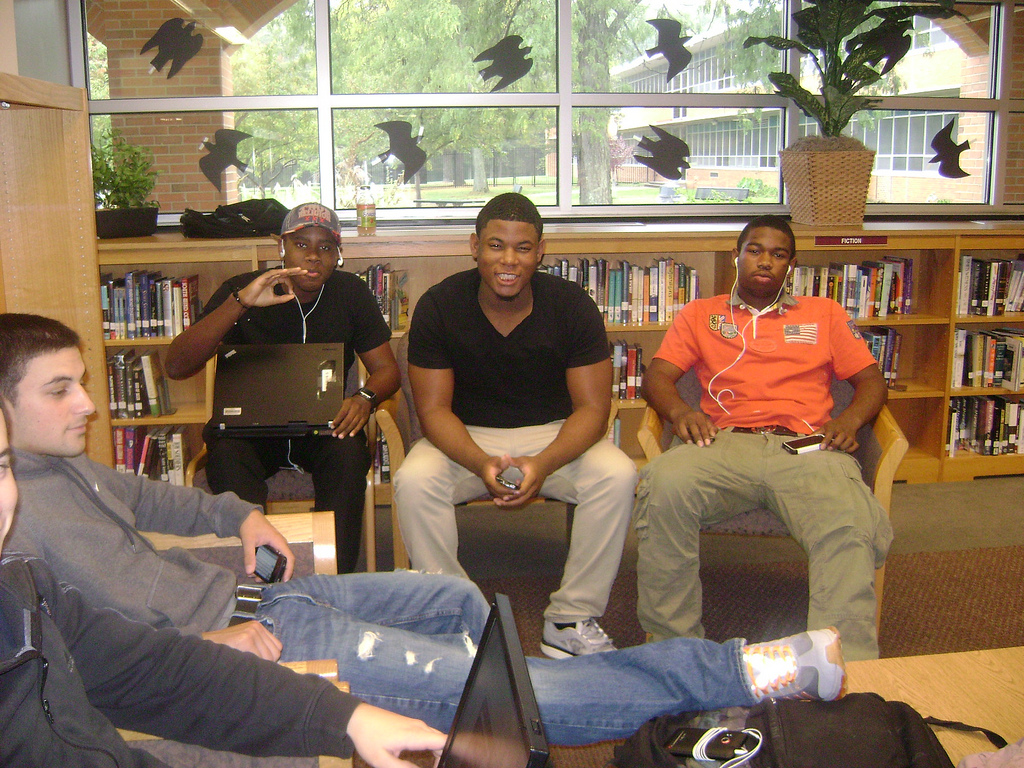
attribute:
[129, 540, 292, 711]
belt — dark-colored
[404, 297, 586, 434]
shirt — black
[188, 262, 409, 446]
shirt — black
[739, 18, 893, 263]
plant — potted , brown 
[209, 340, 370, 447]
laptop — black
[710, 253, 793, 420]
headphones — white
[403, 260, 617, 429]
shirt — short-sleeved, man's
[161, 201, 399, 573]
man — young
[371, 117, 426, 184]
bird — black, paper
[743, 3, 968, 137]
plant — small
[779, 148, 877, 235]
wicker basket — brown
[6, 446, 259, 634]
jacket — grey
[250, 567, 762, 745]
jeans — blue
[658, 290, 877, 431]
shirt — orange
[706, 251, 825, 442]
earphones — white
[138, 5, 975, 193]
birds — black, paper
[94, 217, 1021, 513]
shelf — beige, wooden